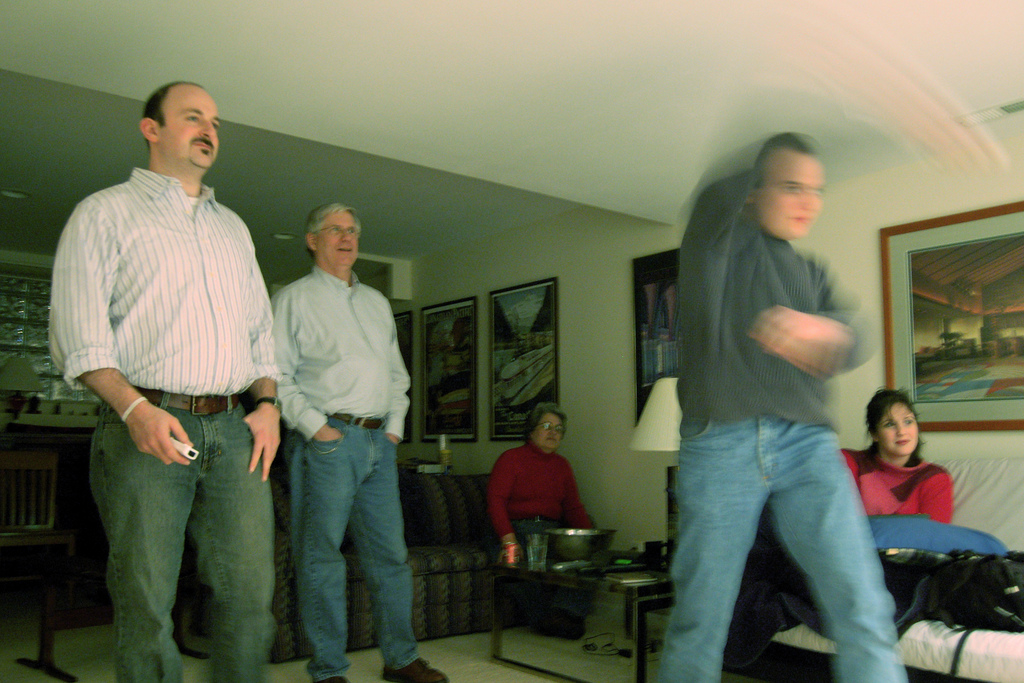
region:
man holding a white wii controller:
[43, 79, 282, 680]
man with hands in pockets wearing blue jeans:
[266, 200, 454, 679]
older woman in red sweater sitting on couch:
[475, 398, 602, 642]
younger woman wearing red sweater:
[833, 382, 957, 526]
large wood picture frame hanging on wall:
[877, 181, 1021, 429]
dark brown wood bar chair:
[1, 445, 78, 680]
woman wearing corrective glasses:
[484, 399, 599, 638]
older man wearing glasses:
[263, 199, 453, 680]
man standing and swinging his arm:
[648, 126, 914, 678]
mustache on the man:
[177, 134, 231, 151]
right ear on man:
[139, 112, 163, 152]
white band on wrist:
[116, 385, 146, 431]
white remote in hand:
[152, 429, 207, 462]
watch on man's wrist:
[252, 388, 284, 414]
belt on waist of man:
[125, 384, 262, 416]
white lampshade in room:
[629, 362, 690, 465]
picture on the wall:
[473, 276, 572, 457]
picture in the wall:
[416, 293, 481, 452]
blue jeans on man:
[287, 416, 428, 676]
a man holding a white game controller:
[137, 411, 205, 478]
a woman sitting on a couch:
[490, 396, 576, 553]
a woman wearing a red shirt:
[490, 439, 576, 516]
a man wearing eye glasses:
[311, 219, 372, 252]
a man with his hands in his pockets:
[311, 393, 411, 480]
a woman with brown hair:
[857, 395, 931, 462]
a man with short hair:
[142, 80, 210, 125]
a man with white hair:
[311, 203, 363, 238]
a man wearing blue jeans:
[307, 418, 416, 654]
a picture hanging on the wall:
[478, 256, 568, 450]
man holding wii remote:
[46, 75, 296, 676]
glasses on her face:
[536, 407, 572, 431]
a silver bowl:
[546, 527, 614, 567]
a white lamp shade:
[622, 375, 687, 443]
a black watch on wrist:
[258, 392, 293, 419]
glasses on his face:
[302, 214, 364, 238]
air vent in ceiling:
[945, 94, 1022, 139]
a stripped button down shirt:
[56, 162, 285, 410]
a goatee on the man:
[185, 132, 224, 172]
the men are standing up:
[52, 81, 912, 680]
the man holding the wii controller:
[43, 82, 281, 680]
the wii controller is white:
[168, 432, 200, 462]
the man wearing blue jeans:
[272, 199, 446, 680]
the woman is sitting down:
[485, 402, 600, 557]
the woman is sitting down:
[740, 385, 955, 680]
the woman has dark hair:
[727, 380, 955, 676]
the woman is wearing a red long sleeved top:
[722, 385, 953, 674]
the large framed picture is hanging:
[876, 199, 1022, 434]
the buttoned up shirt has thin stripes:
[48, 162, 280, 398]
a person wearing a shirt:
[684, 164, 852, 632]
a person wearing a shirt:
[308, 178, 486, 435]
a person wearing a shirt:
[55, 120, 294, 468]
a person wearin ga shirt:
[500, 398, 609, 550]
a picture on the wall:
[864, 176, 1016, 405]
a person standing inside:
[584, 149, 978, 677]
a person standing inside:
[272, 189, 418, 642]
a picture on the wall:
[498, 204, 660, 518]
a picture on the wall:
[400, 261, 528, 480]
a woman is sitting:
[461, 382, 607, 671]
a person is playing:
[63, 67, 316, 660]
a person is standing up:
[48, 74, 290, 667]